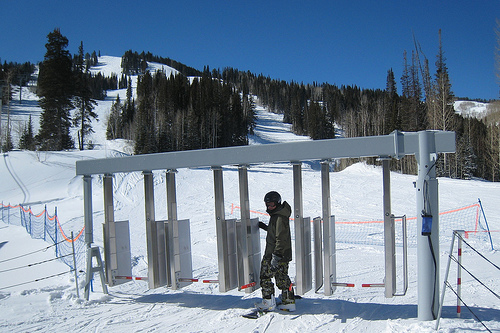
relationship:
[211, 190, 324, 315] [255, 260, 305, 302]
man has pants